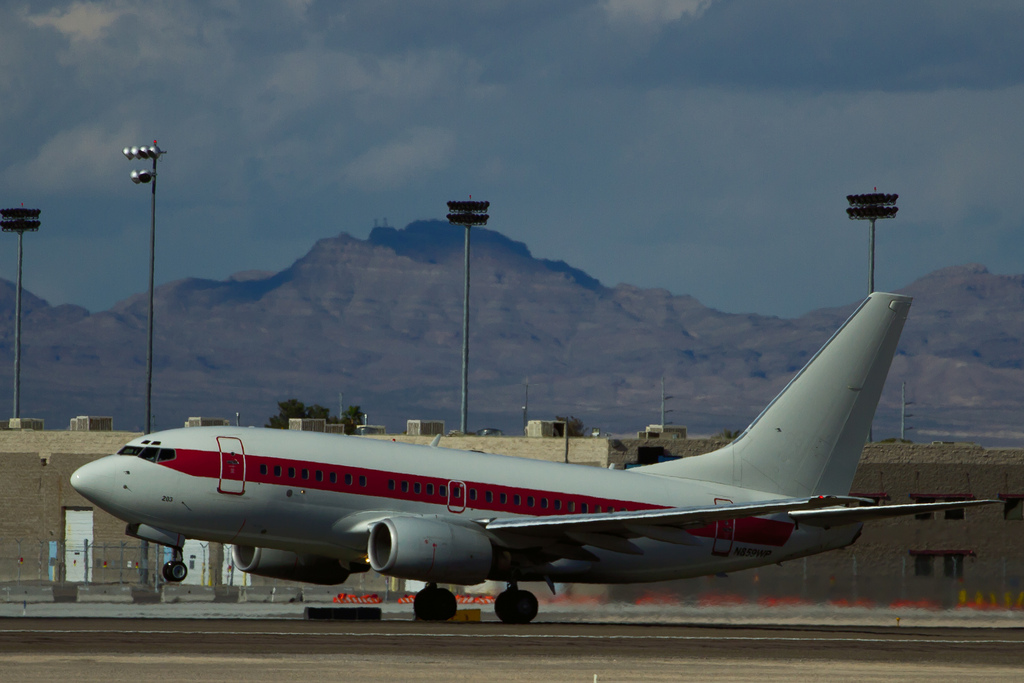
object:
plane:
[68, 287, 1016, 631]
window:
[257, 460, 271, 476]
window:
[299, 465, 310, 482]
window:
[343, 470, 355, 488]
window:
[358, 471, 371, 488]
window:
[385, 475, 399, 494]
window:
[413, 479, 426, 495]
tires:
[411, 585, 461, 623]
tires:
[485, 581, 548, 628]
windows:
[328, 468, 344, 487]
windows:
[298, 465, 314, 481]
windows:
[551, 498, 564, 512]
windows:
[539, 495, 552, 512]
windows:
[480, 489, 496, 504]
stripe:
[333, 597, 380, 605]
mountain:
[2, 203, 1024, 470]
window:
[271, 463, 287, 478]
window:
[287, 463, 298, 479]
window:
[314, 465, 328, 483]